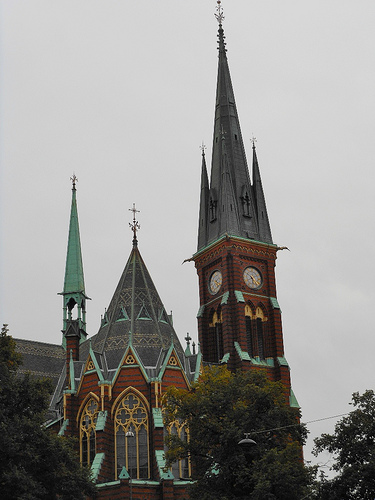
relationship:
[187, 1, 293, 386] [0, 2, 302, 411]
tower on roof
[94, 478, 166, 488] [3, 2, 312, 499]
edge of building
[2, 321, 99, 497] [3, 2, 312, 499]
tree in front of building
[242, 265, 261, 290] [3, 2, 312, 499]
clock on building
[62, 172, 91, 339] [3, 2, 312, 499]
spire on top of building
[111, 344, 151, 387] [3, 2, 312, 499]
triangle on top of building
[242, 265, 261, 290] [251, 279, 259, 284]
clock with hand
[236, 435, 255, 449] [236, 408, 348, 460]
lamp on power line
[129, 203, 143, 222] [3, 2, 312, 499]
cross on top of building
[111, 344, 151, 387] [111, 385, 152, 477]
triangle above window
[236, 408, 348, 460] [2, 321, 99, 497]
power line by tree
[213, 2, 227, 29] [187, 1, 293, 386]
weather vane on top of tower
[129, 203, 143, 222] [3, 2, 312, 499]
cross on top building